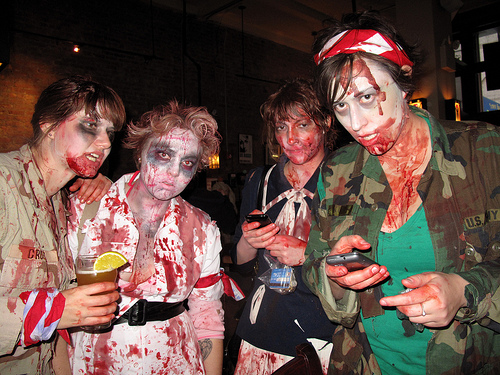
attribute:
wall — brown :
[0, 27, 274, 158]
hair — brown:
[262, 78, 332, 155]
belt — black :
[107, 285, 193, 330]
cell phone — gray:
[308, 242, 408, 302]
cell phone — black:
[251, 209, 278, 256]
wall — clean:
[3, 69, 30, 116]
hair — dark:
[322, 54, 353, 110]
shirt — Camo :
[424, 110, 498, 326]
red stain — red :
[364, 116, 435, 230]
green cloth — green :
[358, 202, 436, 370]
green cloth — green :
[418, 119, 498, 366]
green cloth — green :
[304, 138, 390, 368]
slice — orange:
[92, 249, 129, 274]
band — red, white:
[309, 24, 411, 69]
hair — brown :
[28, 74, 125, 128]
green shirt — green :
[355, 220, 440, 298]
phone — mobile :
[323, 251, 379, 277]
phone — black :
[242, 206, 276, 243]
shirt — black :
[249, 161, 336, 349]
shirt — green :
[371, 207, 451, 368]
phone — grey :
[316, 243, 392, 284]